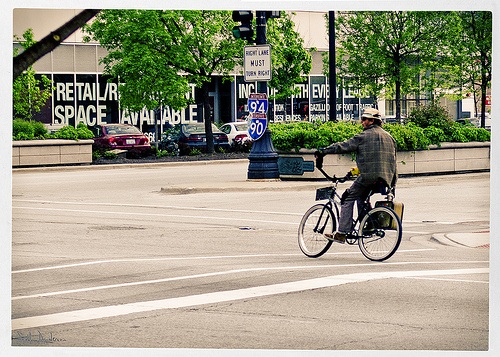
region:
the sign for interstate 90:
[246, 108, 273, 144]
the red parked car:
[90, 118, 152, 156]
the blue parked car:
[170, 118, 230, 153]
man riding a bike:
[299, 106, 411, 269]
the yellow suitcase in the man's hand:
[367, 185, 413, 232]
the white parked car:
[219, 118, 251, 148]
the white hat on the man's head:
[356, 99, 385, 129]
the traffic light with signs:
[227, 8, 281, 178]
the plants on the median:
[273, 120, 488, 175]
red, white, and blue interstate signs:
[243, 88, 275, 143]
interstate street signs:
[241, 89, 269, 151]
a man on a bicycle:
[296, 100, 412, 265]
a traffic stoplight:
[220, 3, 285, 184]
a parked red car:
[72, 115, 167, 165]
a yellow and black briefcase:
[351, 188, 407, 234]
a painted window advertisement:
[48, 71, 205, 132]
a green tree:
[90, 7, 302, 162]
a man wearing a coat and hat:
[311, 101, 397, 241]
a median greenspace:
[251, 103, 492, 181]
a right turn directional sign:
[234, 42, 276, 88]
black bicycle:
[297, 155, 401, 264]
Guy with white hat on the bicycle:
[311, 107, 398, 242]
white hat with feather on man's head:
[359, 106, 383, 118]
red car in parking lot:
[92, 122, 149, 157]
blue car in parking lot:
[162, 121, 229, 151]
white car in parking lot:
[220, 120, 257, 150]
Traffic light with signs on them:
[230, 10, 280, 181]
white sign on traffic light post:
[241, 45, 269, 81]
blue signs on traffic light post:
[245, 90, 266, 138]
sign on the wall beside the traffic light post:
[276, 157, 316, 176]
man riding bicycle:
[297, 108, 402, 260]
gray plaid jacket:
[320, 126, 398, 187]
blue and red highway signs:
[245, 92, 269, 139]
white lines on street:
[11, 196, 491, 331]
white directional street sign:
[243, 44, 270, 81]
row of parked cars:
[90, 122, 252, 157]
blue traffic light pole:
[232, 11, 281, 179]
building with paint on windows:
[55, 80, 372, 123]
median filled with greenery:
[271, 121, 487, 179]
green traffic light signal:
[232, 24, 252, 39]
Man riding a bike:
[290, 90, 414, 277]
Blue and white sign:
[242, 84, 277, 120]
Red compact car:
[84, 102, 158, 164]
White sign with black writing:
[235, 34, 280, 96]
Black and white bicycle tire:
[354, 198, 409, 268]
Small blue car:
[159, 98, 235, 164]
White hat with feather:
[353, 96, 399, 130]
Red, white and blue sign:
[239, 111, 278, 141]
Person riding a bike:
[291, 96, 413, 264]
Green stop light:
[225, 19, 260, 41]